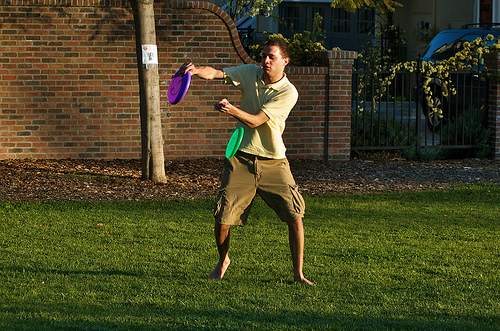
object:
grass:
[1, 181, 498, 329]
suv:
[418, 17, 499, 129]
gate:
[349, 52, 488, 155]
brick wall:
[0, 0, 359, 160]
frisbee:
[222, 127, 245, 159]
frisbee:
[165, 60, 192, 106]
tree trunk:
[128, 1, 169, 183]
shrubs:
[349, 102, 491, 157]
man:
[181, 37, 316, 287]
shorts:
[213, 150, 305, 225]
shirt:
[219, 63, 300, 160]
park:
[1, 1, 499, 331]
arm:
[227, 87, 298, 128]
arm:
[194, 63, 254, 82]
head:
[259, 37, 291, 76]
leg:
[286, 213, 306, 275]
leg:
[213, 220, 232, 256]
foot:
[294, 272, 317, 288]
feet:
[210, 253, 233, 278]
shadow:
[2, 296, 498, 331]